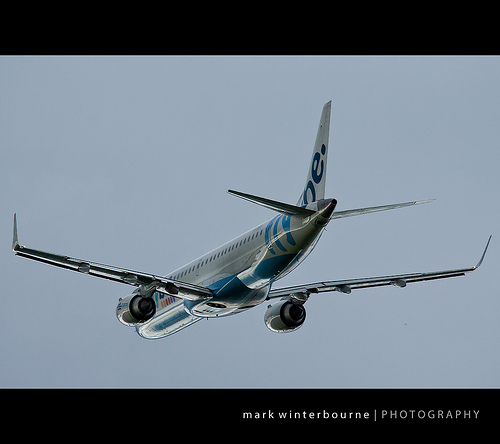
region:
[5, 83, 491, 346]
airplane in the sky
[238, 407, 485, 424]
white text on the bottom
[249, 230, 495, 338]
right wing of the plane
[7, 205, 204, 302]
left wing of the plane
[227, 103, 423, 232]
tail of the airplane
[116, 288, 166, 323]
left jet of the plane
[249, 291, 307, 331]
right jet of the plane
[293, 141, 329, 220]
blue text on the tail of the plane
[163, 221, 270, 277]
passenger windows on the plane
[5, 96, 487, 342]
a passenger airplane in the sky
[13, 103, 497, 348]
plane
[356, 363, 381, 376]
white clouds in blue sky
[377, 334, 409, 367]
white clouds in blue sky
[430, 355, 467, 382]
white clouds in blue sky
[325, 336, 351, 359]
white clouds in blue sky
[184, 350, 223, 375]
white clouds in blue sky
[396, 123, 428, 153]
white clouds in blue sky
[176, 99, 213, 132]
white clouds in blue sky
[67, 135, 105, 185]
white clouds in blue sky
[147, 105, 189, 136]
white clouds in blue sky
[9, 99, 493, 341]
A blue and white passenger jet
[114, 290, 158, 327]
The left jet engine of a plane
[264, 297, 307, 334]
The right jet engine of a plane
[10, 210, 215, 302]
The left wing of the plane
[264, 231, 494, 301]
The right wing of the plane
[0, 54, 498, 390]
A clear blue sky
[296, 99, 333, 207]
The tail fin of the plane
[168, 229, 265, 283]
The row of windows on a plane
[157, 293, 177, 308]
A row of multi colors on a plane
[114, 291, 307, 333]
The jet engines on a plane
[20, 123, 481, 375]
plane in the air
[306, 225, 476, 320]
wing of the plane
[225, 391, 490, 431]
words in bottom right corner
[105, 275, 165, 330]
engine of the plane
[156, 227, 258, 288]
windows on the plane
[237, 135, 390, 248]
tail of the plane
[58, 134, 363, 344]
blue and silver plane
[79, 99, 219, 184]
sky above the plane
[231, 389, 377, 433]
white text in photo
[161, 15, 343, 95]
black bar in photo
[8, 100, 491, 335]
an airplane flying through the sky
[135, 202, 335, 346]
the airplane's fuselage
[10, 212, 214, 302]
the airplane's left wing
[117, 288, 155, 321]
jet engine on left wing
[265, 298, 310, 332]
jet engine on right wing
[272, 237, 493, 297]
right airplane wing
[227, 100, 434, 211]
tail of airplane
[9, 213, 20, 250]
winglet on left wingtip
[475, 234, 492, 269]
winglet on right wingtip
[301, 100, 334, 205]
the airplane's fin